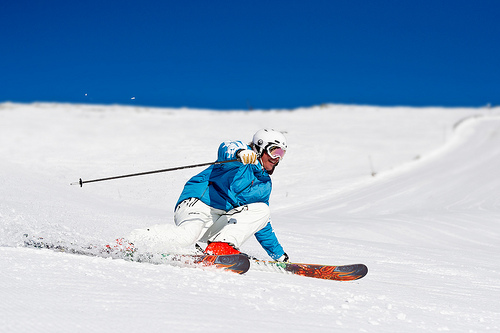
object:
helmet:
[251, 127, 289, 157]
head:
[251, 128, 288, 171]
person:
[109, 127, 289, 264]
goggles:
[267, 144, 287, 159]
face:
[261, 144, 284, 172]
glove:
[239, 149, 258, 165]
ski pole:
[69, 155, 263, 187]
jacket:
[172, 139, 286, 262]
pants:
[122, 196, 272, 250]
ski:
[249, 259, 369, 282]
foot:
[204, 241, 246, 256]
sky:
[0, 0, 499, 99]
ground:
[1, 102, 499, 332]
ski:
[23, 234, 251, 275]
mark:
[296, 130, 499, 251]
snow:
[1, 207, 220, 268]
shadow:
[198, 160, 238, 244]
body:
[117, 127, 291, 261]